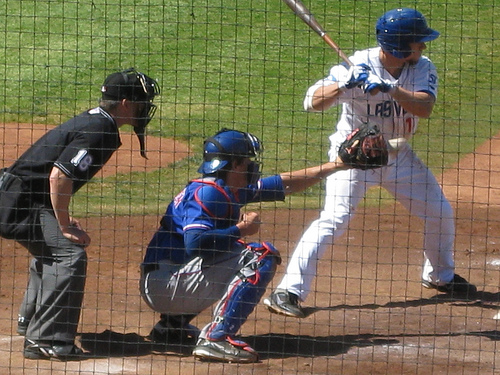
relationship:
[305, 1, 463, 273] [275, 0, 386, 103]
player holding bat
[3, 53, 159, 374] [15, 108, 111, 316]
umpire has uniform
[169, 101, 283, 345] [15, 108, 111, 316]
catcher has uniform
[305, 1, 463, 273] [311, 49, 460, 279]
player has uniform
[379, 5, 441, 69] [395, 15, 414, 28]
helmet royal blue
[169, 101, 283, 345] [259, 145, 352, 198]
catcher extending arm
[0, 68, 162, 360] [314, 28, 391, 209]
umpire playing baseball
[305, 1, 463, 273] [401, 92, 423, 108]
man light skinned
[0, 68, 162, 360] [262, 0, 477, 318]
umpire semi professional player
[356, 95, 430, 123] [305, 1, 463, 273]
las vegas baseball team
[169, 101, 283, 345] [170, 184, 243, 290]
team opposing uniform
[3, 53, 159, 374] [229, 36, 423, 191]
umpire in a game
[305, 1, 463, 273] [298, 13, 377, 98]
player ready to hit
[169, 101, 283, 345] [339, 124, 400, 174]
catcher ready to receive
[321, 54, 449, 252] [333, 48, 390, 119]
technique for hitting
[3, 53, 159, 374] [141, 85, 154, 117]
umpire closely watching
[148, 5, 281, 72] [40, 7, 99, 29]
baseball field in background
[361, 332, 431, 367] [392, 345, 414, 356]
homeplate barely seen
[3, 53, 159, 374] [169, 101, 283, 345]
umpire over catcher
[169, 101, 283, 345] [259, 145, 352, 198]
catcher extended arm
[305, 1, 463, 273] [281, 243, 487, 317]
batter in box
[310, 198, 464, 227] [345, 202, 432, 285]
legs spread open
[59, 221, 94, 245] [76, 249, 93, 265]
hand on knee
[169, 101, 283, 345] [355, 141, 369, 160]
catcher mit black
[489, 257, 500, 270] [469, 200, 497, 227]
white dust in dirt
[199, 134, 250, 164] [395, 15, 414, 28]
hat shiny blue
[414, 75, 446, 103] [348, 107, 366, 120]
short sleeved shirt white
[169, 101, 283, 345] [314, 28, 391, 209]
catcher playing baseball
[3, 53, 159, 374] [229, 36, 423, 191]
umpire at a game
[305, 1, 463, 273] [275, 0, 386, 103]
batter with a bat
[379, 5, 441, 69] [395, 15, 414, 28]
helmet baseball blue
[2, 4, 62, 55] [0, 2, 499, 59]
grass on a field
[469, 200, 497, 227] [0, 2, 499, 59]
dirt on a field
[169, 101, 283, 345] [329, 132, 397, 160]
player has mitt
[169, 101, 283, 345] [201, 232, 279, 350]
catcher has knee guard